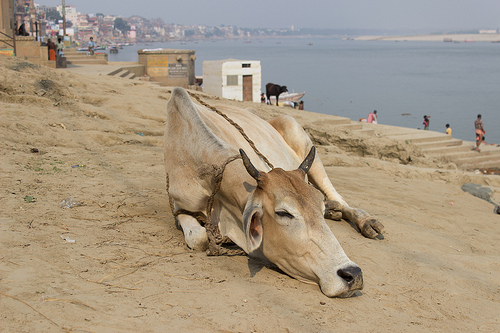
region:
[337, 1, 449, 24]
this is the sky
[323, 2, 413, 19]
the sky is full of clouds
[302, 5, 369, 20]
the clouds are white in color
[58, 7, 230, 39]
these are some buildings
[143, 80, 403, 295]
this is a cow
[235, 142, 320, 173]
these are the horns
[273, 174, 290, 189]
the fur is brown in color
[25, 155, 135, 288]
this is the ground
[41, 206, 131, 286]
the ground is full of sand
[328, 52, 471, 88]
this is the water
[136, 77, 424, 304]
A cow laying in the dirt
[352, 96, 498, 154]
People near the water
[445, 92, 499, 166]
A person standing on steps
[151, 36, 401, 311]
A cow with horns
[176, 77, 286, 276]
A rope on a cow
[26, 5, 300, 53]
Buildings in the disance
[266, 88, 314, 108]
A boat in the water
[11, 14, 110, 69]
People in the background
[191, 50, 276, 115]
A shack behind the cow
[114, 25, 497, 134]
A large body of water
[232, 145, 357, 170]
Animal has dark horns.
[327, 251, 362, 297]
Animal has black nose.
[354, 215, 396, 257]
Animal has brown hooves.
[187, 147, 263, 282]
Animal has rope around body.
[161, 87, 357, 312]
Large animal laying in sand.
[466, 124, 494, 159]
Person wearing pink and black swim suit.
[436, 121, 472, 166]
Person wearing yellow shirt.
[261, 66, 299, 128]
Large black animal standing in sand.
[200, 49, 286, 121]
White building near large animal.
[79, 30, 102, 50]
Person wearing light blue shirt.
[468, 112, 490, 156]
a man by the water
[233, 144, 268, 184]
black horn of a cow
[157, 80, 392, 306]
cow laying on the dirt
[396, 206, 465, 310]
brown dirt covers the ground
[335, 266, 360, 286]
large nostril of a cow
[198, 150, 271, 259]
a rope around the neck of a cow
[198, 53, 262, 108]
a white building with brown door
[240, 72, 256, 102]
brown door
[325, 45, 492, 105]
a large body of water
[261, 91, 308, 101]
a boat in the water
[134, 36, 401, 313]
the cow on the beach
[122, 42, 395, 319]
the cow is tan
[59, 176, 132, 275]
the sand is golden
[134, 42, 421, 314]
the cow has horns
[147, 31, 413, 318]
the cow is sleeping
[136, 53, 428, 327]
cow horns are black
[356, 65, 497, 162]
people are at the river bank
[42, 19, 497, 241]
steps leading down to the water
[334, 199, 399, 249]
the cow has cloven hooves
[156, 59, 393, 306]
the cow has a rope around the neck